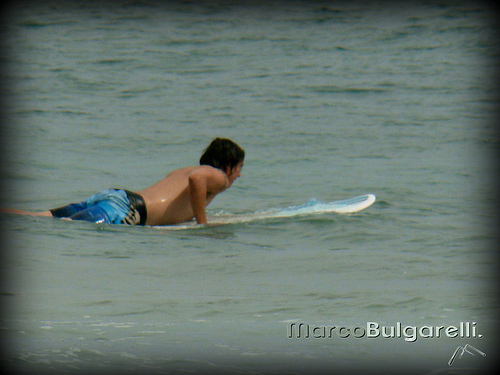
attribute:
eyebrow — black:
[237, 159, 251, 169]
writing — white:
[364, 320, 484, 342]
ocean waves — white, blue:
[15, 13, 488, 359]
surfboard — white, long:
[164, 192, 405, 232]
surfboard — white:
[132, 188, 376, 228]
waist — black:
[120, 182, 155, 232]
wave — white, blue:
[27, 25, 465, 137]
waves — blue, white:
[54, 276, 428, 325]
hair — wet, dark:
[198, 134, 241, 168]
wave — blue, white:
[285, 77, 488, 96]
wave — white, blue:
[8, 291, 185, 329]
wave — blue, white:
[158, 299, 488, 327]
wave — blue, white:
[266, 68, 497, 106]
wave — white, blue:
[142, 31, 317, 57]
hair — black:
[198, 132, 245, 170]